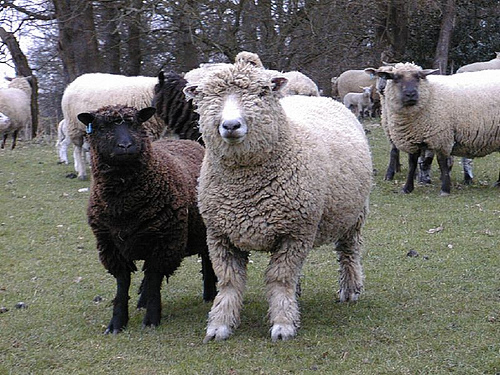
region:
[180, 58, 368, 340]
a standing white sheep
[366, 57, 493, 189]
a standing white sheep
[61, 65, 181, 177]
a standing white sheep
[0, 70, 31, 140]
a standing white sheep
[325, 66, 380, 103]
a standing white sheep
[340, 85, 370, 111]
a standing white sheep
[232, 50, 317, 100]
a standing white sheep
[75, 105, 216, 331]
a standing black sheep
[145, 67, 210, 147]
a standing black sheep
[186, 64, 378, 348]
a thick wooled sheep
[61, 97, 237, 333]
small sheep with black wool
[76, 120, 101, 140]
small blue ear tag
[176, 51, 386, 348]
large sheep with white wool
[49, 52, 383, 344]
black and white sheep standing together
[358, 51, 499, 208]
white sheep with black face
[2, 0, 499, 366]
flock of sheep in field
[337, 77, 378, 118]
baby sheep near mother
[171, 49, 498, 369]
sheep standing in a field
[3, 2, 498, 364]
sheep in the grass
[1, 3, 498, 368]
sheep standing near a forest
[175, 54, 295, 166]
the head of a white sheep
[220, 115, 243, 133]
the nose of a white sheep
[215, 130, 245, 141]
the mouth of a sheep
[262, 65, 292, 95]
the ear of a sheep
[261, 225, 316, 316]
the leg of a sheep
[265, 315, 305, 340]
the hoof of a sheep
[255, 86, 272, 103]
the eye of a sheep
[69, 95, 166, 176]
the head of a black sheep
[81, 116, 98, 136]
a blue ear tag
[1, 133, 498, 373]
a grassy green field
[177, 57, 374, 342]
A sheep looking at the camera.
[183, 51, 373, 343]
A white sheep looking at the camera.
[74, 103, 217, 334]
A dark brown sheep looking at the camera.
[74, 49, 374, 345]
Two sheep looking at the camera.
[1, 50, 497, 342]
Sheep in a field.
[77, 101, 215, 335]
A sheep looking at the camera.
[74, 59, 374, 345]
Sheep standing in a field.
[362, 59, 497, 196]
A sheep standing in a field.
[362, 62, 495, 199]
A sheep facing the camera.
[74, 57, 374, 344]
Two sheep standing in a field facing the camera.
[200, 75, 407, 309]
sheep has wool all over his body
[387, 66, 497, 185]
sheep doesn't have wool on his legs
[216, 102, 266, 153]
sheep has a white face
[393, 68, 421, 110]
sheep has a black face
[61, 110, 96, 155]
sheep has a tag in his ear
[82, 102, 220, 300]
sheep has brown wool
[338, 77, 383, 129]
baby sheep next to a parent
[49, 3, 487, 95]
trees behind the sheep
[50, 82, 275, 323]
two brown sheep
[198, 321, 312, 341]
hoofs of the sheep